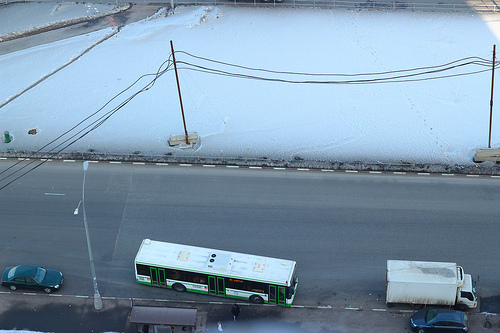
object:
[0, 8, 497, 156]
snow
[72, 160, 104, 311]
light pole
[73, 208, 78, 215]
lamp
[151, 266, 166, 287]
doors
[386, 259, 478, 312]
truck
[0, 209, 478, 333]
traffic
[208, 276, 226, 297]
doors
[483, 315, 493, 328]
person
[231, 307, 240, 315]
jacket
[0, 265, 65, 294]
car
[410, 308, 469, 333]
blue car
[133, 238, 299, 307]
bus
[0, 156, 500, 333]
pavement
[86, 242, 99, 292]
pole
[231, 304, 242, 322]
person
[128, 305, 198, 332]
building